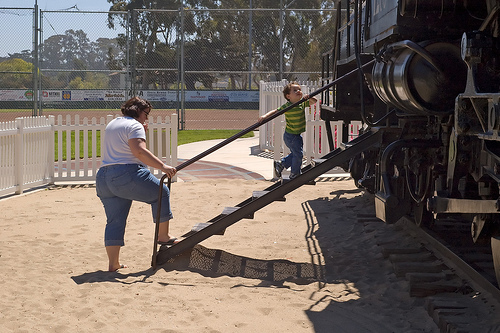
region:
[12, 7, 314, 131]
a large chain link fence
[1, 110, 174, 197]
a white fence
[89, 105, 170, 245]
a lady wearing a white shirt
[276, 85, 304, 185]
a child wearing a striped shirt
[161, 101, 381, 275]
stairs going up to the train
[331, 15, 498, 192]
a black train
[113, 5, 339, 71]
tall trees in the background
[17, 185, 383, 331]
sand next to the train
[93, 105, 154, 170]
woman wearing a white shirt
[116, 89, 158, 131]
woman with brown hair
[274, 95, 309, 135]
boy wearing a striped shirt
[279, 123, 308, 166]
boy wearing blue pants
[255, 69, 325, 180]
boy entering a train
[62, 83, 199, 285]
woman holding a hand rail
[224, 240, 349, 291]
shadow on the ground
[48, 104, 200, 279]
a woman going up some stairs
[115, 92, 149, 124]
the head of an adult woman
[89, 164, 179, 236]
the pants of an adult woman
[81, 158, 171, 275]
the legs of an adult woman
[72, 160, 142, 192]
the butt of an adult woman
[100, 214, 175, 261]
the calves of an adult woman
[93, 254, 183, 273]
the feet of an adult woman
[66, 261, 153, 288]
the shadow of an adult woman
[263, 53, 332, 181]
a small little toddler boy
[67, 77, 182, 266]
A woman in the photo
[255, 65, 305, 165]
A boy on the staircase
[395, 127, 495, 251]
Train wheels in the photo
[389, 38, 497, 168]
A train in the photo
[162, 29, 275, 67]
Wire mesh on the fence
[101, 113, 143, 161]
White top in the photo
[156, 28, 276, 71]
Trees in the photo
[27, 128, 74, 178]
A wooden fence in the photo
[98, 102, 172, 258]
A woman on the staircase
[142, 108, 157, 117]
Glasses on the eyes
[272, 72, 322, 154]
A boy on the staircase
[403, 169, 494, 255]
Wheels of a train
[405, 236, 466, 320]
Track ballast in the photo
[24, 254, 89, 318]
Sand on the ground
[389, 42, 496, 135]
A train in the photo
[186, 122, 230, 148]
Grass in the photo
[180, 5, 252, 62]
Wire mesh on the fence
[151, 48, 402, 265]
a kid walking on stairs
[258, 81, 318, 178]
a kid in a green shirt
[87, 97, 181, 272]
a woman with a white shirt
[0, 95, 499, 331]
a woman on top of sand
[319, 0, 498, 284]
a large black train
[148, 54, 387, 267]
a black and metal hand rail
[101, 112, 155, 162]
a woman wearing a white shirt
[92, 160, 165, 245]
a woman wearing blue jeans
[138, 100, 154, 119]
a woman wearing eye glasses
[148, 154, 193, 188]
a woman with her hand on a hand rail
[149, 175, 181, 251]
a woman with her foot on a step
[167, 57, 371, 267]
a set of metal stairs to a train car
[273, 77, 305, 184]
a young boy on steps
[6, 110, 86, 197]
a white picket fence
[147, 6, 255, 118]
a chain link fence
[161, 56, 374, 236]
a metal hand rail